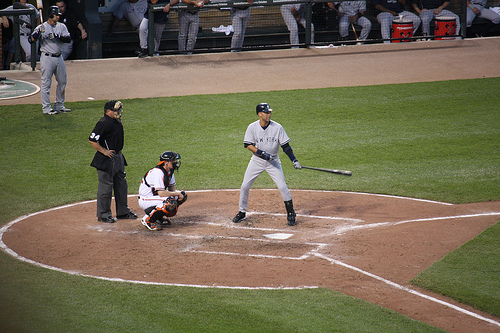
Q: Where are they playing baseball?
A: Field.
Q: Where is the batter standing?
A: Batters box.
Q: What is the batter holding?
A: Bat.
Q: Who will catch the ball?
A: Catcher.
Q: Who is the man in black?
A: Umpire.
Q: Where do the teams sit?
A: Dugout.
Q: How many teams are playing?
A: Two.